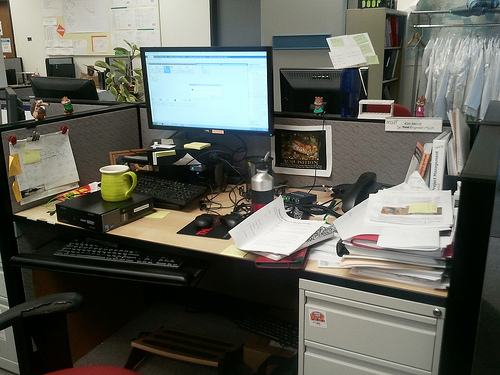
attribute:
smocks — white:
[419, 33, 498, 120]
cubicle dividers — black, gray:
[0, 103, 169, 373]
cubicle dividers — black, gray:
[442, 124, 497, 374]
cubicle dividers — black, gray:
[136, 102, 473, 192]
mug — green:
[92, 159, 137, 219]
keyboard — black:
[54, 236, 182, 270]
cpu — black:
[56, 189, 156, 234]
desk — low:
[95, 125, 440, 347]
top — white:
[426, 41, 436, 99]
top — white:
[440, 40, 445, 105]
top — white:
[470, 47, 482, 114]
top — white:
[484, 42, 493, 64]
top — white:
[488, 52, 496, 103]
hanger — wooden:
[383, 17, 434, 53]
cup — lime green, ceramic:
[98, 162, 135, 201]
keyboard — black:
[9, 240, 194, 285]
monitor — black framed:
[132, 45, 292, 139]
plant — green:
[90, 39, 147, 110]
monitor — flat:
[142, 41, 275, 152]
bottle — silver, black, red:
[247, 155, 277, 210]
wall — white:
[32, 17, 146, 66]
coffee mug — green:
[90, 160, 142, 209]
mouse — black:
[196, 210, 239, 239]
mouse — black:
[207, 210, 239, 237]